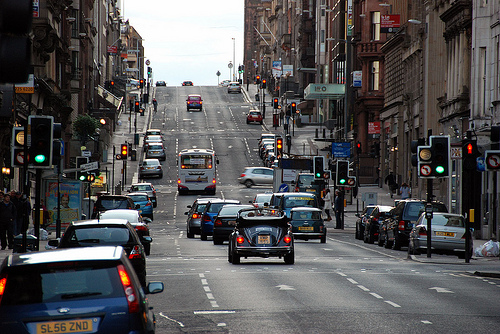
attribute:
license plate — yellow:
[31, 316, 108, 333]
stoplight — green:
[25, 114, 55, 166]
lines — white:
[191, 267, 228, 319]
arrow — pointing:
[260, 282, 308, 301]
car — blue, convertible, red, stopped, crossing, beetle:
[231, 186, 294, 262]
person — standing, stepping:
[383, 166, 404, 197]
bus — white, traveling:
[175, 144, 222, 194]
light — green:
[37, 147, 50, 169]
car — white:
[232, 160, 266, 187]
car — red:
[81, 216, 156, 278]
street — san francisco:
[156, 87, 292, 300]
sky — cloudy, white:
[145, 3, 235, 89]